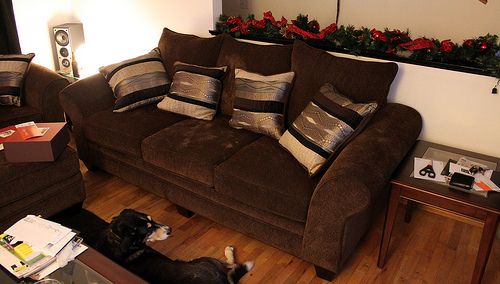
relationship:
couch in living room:
[55, 23, 422, 276] [2, 7, 499, 281]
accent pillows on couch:
[95, 50, 171, 113] [55, 23, 422, 276]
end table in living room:
[371, 136, 499, 278] [2, 7, 499, 281]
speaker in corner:
[46, 13, 86, 79] [12, 0, 145, 77]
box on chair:
[0, 121, 71, 164] [1, 2, 92, 230]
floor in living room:
[72, 154, 500, 284] [2, 7, 499, 281]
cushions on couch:
[86, 99, 320, 229] [55, 23, 422, 276]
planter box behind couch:
[233, 9, 499, 70] [55, 25, 425, 282]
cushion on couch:
[155, 60, 231, 122] [55, 23, 422, 276]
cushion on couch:
[277, 81, 381, 179] [55, 23, 422, 276]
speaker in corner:
[48, 19, 86, 73] [26, 6, 142, 72]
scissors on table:
[417, 150, 435, 180] [362, 135, 498, 282]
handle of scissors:
[413, 161, 440, 182] [414, 149, 439, 186]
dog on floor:
[97, 207, 257, 282] [72, 163, 498, 280]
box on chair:
[9, 117, 69, 167] [1, 50, 89, 230]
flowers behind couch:
[225, 10, 498, 76] [55, 23, 422, 276]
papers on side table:
[410, 154, 499, 196] [368, 137, 496, 282]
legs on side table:
[368, 200, 498, 277] [368, 137, 496, 282]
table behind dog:
[1, 216, 151, 282] [97, 207, 257, 282]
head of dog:
[106, 206, 176, 248] [97, 207, 257, 282]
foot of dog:
[224, 246, 234, 256] [97, 207, 257, 282]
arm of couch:
[297, 102, 426, 282] [55, 23, 422, 276]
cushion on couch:
[286, 38, 399, 165] [55, 23, 422, 276]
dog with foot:
[97, 207, 257, 282] [220, 243, 239, 272]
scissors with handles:
[419, 159, 437, 178] [416, 163, 438, 181]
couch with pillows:
[55, 25, 425, 282] [90, 49, 380, 175]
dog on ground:
[97, 207, 257, 282] [56, 133, 484, 281]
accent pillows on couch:
[94, 45, 380, 175] [55, 25, 425, 282]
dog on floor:
[97, 207, 257, 282] [74, 120, 484, 281]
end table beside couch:
[374, 139, 500, 284] [55, 25, 425, 282]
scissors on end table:
[419, 159, 437, 178] [374, 139, 500, 284]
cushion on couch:
[224, 60, 302, 140] [55, 23, 422, 276]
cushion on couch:
[156, 58, 228, 128] [55, 23, 422, 276]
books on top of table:
[0, 202, 90, 278] [0, 219, 155, 280]